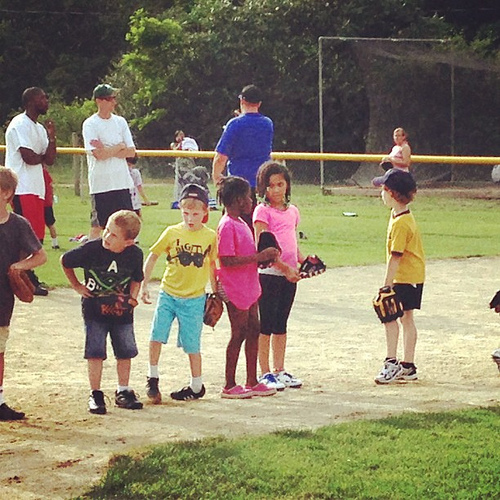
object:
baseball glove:
[373, 287, 404, 323]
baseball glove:
[297, 254, 324, 281]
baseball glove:
[257, 231, 280, 266]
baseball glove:
[199, 293, 227, 328]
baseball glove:
[100, 290, 134, 316]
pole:
[303, 148, 498, 165]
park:
[4, 2, 499, 342]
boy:
[150, 190, 220, 425]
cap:
[242, 84, 264, 102]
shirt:
[214, 215, 262, 311]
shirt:
[251, 203, 300, 270]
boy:
[60, 211, 145, 414]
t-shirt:
[62, 237, 145, 325]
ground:
[2, 253, 493, 455]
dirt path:
[180, 390, 223, 434]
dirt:
[45, 450, 93, 470]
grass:
[288, 439, 419, 486]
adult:
[83, 82, 137, 238]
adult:
[7, 85, 50, 296]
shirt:
[83, 115, 134, 193]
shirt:
[3, 113, 48, 197]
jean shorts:
[81, 313, 136, 358]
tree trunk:
[341, 37, 461, 182]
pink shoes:
[224, 385, 251, 400]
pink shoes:
[248, 382, 275, 397]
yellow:
[405, 247, 418, 275]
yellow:
[169, 269, 193, 291]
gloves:
[7, 267, 48, 302]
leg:
[83, 304, 108, 391]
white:
[102, 122, 125, 138]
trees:
[10, 1, 499, 183]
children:
[0, 167, 46, 417]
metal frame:
[316, 31, 478, 186]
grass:
[288, 407, 469, 494]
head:
[239, 85, 264, 112]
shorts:
[149, 287, 205, 352]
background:
[15, 16, 483, 294]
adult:
[210, 84, 275, 210]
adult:
[377, 127, 412, 176]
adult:
[169, 131, 199, 206]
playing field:
[4, 177, 484, 491]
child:
[211, 173, 280, 401]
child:
[249, 158, 303, 391]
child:
[373, 168, 426, 384]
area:
[97, 414, 497, 497]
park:
[3, 178, 495, 498]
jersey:
[150, 222, 217, 296]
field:
[0, 183, 499, 497]